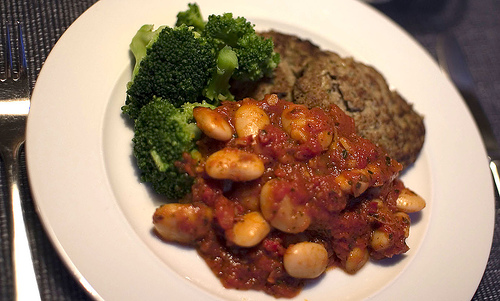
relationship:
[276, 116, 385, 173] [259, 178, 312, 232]
sauce covering bean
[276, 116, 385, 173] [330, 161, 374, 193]
sauce covering bean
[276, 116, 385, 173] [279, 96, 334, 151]
sauce covering bean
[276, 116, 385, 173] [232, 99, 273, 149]
sauce covering bean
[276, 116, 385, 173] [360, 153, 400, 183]
sauce covering bean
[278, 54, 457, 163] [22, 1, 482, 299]
meat lying on top of plate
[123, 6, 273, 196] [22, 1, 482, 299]
broccoli lying on top of plate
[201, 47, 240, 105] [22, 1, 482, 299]
broccoli lying on top of plate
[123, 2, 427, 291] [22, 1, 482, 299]
food lying on top of plate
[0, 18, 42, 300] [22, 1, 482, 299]
fork lying next to plate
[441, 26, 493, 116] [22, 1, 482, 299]
knife lying next to plate